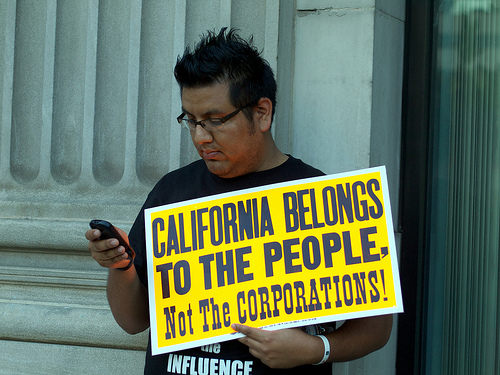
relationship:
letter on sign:
[214, 247, 235, 285] [134, 159, 406, 360]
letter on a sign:
[303, 234, 321, 270] [119, 172, 431, 351]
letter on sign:
[153, 255, 182, 313] [128, 144, 479, 374]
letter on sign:
[171, 258, 192, 296] [134, 159, 406, 360]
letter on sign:
[232, 247, 257, 284] [146, 192, 398, 328]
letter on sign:
[262, 240, 281, 276] [144, 125, 417, 342]